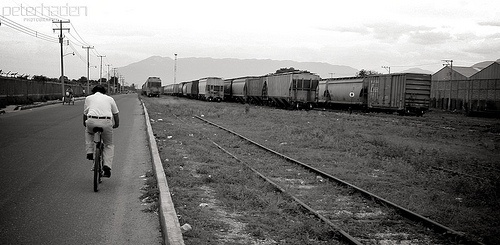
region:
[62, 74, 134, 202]
man riding a bicycle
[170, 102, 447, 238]
empty railroad tracks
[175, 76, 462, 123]
cargo train on the tracks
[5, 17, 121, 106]
power lines on the side of the road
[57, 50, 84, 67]
a street lamp on a telephone pole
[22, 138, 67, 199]
asphalt road for traveling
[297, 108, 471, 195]
grass growing in between train tracks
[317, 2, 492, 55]
whispy clouds in the sky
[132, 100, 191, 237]
curb separating road from train tracks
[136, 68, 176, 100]
an engine of a train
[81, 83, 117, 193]
a man riding bicycle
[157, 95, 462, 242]
a set of train tracks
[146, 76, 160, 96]
a train engine in distance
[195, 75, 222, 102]
a train car on tracks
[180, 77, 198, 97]
a train car on tracks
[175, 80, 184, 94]
a train car on tracks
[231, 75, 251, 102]
a train car on tracks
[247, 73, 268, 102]
a train car on tracks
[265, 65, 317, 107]
a train car on tracks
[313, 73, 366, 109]
a train car on tracks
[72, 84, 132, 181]
man cycling near train track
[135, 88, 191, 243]
stone rail next to tracks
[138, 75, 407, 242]
train on track in distance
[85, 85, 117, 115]
man has light shirt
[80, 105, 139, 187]
man has dark belt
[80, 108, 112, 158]
man has dark pants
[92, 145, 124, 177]
man has dark shoes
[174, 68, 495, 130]
numerous train cars on tracks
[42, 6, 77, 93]
telephone pole left of man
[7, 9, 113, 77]
many wires between poles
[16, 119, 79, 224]
The street is made of ashpalt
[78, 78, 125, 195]
The man is riding the bike down the street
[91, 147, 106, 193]
The back tire of the bike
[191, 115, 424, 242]
The train tracks are made of iron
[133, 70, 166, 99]
The train is traveling forward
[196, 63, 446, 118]
The trains have been abandoned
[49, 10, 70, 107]
An electrical pole on the side of the road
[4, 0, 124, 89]
The electrical wires are black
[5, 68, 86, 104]
The fence along side of the road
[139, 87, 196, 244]
The cement separates the street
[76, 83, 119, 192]
man rides bicycle next to train tracks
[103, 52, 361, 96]
a far off mountain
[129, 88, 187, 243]
curb divides road from train tracks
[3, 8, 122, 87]
poles for utility lines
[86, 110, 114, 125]
a black waist belt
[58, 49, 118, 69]
a line of street lights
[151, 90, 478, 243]
overgrown train tracks and litter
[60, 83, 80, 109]
a person on a three wheel bicycle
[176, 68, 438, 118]
coal and cargo cars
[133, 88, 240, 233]
litter strewn on ground